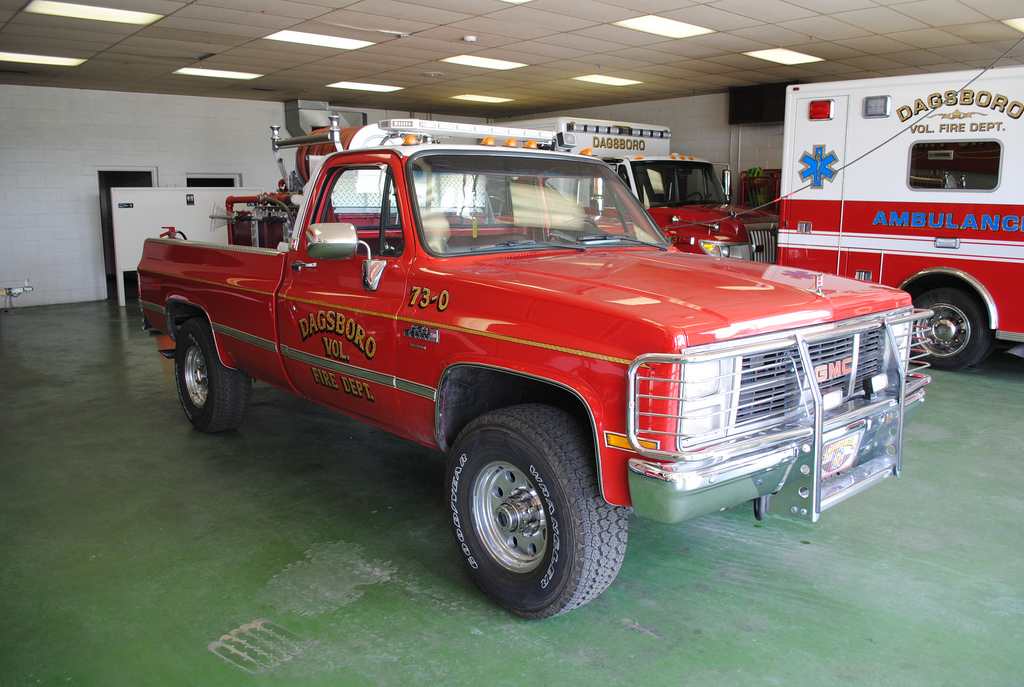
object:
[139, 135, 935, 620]
truck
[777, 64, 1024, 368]
ambulance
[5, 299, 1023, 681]
floor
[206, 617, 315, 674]
tracks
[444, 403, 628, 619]
tire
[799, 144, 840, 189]
symbol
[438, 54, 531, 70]
light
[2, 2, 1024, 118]
ceiling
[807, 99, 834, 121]
light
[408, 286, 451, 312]
73-0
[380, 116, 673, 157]
trailer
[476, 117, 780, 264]
ambulance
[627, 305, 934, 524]
bumper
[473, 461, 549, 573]
rim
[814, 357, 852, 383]
gmc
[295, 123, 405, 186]
hose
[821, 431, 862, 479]
license plate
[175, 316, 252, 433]
tire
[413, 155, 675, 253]
windshield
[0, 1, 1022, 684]
garage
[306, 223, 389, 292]
mirror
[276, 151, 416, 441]
door